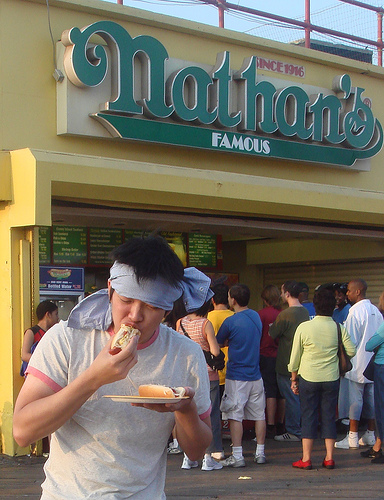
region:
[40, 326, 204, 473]
boy has grey shirt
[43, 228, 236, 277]
green and yellow menu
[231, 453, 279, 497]
pavement is dark grey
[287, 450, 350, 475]
woman has red shoes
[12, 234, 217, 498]
Man eating hot dogs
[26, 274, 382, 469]
People in front of food stand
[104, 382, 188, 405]
Hot dog on a plate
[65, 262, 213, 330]
Large blue band around man's head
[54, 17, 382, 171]
Sign over storefront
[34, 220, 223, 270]
Menu on the wall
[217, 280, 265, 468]
Man with blue shirt and white shorts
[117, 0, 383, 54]
Netting and railing on top of building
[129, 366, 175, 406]
a hotdog on a plate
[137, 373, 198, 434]
a hotdog on a paper plate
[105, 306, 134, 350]
a man eating a hotdog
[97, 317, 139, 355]
a man holding a hotdog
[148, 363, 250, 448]
a man holding a plate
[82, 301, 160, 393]
a man holding and eating a hotdog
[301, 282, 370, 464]
a woman carrying a bag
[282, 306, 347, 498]
a woman wearing red shoes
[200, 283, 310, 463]
a person standing in line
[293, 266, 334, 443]
a person standing in line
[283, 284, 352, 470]
hot dog fan waiting in line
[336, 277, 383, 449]
hot dog fan waiting in line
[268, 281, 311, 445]
hot dog fan waiting in line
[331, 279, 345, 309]
hot dog fan waiting in line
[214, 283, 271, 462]
hot dog fan waiting in line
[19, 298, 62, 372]
hot dog fan waiting in line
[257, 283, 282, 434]
hot dog fan waiting in line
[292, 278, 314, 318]
hot dog fan waiting in line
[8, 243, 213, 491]
man wearing a tshirt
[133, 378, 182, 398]
hot dog on a plate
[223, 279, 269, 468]
man wearing a blue shirt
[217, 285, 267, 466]
man wearing khaki shorts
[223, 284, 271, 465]
man wearing white socks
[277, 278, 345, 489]
woman wearing blue pants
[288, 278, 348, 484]
woman wearing red shoes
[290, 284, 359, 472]
woman holding a purse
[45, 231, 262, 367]
Man wearing headband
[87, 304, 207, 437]
Man eating hotdogs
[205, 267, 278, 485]
Man wearing cargo shorts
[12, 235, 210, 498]
man eating a hot dog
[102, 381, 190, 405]
hot dog on plate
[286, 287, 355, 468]
woman wearing red shoes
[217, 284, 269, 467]
man wearing blue shirt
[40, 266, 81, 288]
hot dog on a sign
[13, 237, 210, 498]
man with cloth tied around head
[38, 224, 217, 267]
green and white signs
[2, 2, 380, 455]
nathan's sign on building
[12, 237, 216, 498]
man bitting a hot dog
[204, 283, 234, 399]
man wearing yellow shirt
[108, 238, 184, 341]
person has a head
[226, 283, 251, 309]
person has a head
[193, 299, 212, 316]
person has a head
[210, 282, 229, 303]
person has a head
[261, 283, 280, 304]
person has a head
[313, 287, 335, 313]
person has a head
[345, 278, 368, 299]
person has a head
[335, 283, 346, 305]
person has a head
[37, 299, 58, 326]
person has a head